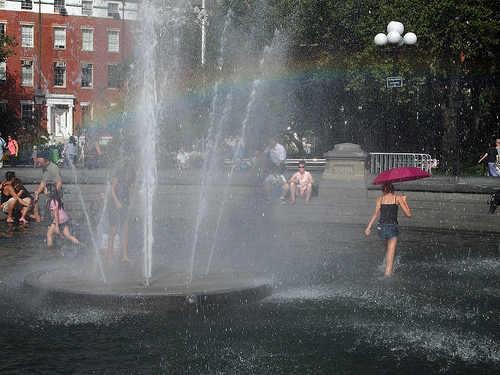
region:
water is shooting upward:
[28, 7, 300, 304]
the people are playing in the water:
[0, 150, 463, 294]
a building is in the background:
[2, 40, 184, 157]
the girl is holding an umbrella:
[358, 161, 440, 290]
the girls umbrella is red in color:
[370, 164, 447, 203]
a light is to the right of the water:
[372, 22, 435, 186]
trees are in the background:
[189, 8, 477, 163]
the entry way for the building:
[43, 93, 76, 146]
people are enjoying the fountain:
[16, 179, 496, 366]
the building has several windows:
[12, 6, 163, 110]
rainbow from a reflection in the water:
[63, 52, 450, 156]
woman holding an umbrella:
[367, 165, 432, 272]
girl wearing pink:
[41, 183, 83, 248]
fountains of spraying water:
[54, 3, 279, 287]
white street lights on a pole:
[374, 20, 417, 52]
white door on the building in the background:
[51, 103, 68, 135]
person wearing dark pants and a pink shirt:
[6, 134, 21, 168]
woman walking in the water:
[366, 165, 432, 274]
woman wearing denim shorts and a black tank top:
[365, 169, 421, 274]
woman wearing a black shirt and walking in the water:
[108, 165, 139, 268]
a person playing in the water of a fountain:
[40, 182, 77, 247]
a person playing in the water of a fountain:
[100, 160, 137, 266]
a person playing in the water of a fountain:
[363, 183, 408, 277]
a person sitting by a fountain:
[293, 161, 313, 201]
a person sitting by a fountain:
[261, 162, 290, 203]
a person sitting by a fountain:
[2, 172, 28, 222]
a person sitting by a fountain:
[10, 178, 35, 222]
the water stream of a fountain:
[62, 131, 113, 281]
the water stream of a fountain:
[125, 12, 163, 283]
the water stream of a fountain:
[189, 42, 231, 274]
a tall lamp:
[370, 16, 426, 148]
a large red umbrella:
[364, 163, 434, 185]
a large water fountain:
[3, 213, 497, 373]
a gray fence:
[367, 154, 427, 174]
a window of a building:
[54, 25, 67, 49]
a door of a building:
[50, 107, 70, 137]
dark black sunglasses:
[296, 163, 306, 170]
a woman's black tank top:
[377, 196, 402, 222]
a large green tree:
[157, 0, 495, 167]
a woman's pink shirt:
[5, 140, 20, 152]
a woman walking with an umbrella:
[356, 150, 431, 292]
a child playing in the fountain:
[35, 184, 101, 261]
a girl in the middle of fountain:
[102, 139, 162, 287]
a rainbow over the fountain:
[98, 79, 321, 113]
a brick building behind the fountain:
[10, 19, 154, 153]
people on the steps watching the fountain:
[256, 139, 336, 219]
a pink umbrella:
[376, 161, 437, 189]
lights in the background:
[346, 9, 443, 104]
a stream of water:
[177, 12, 217, 289]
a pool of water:
[303, 253, 455, 352]